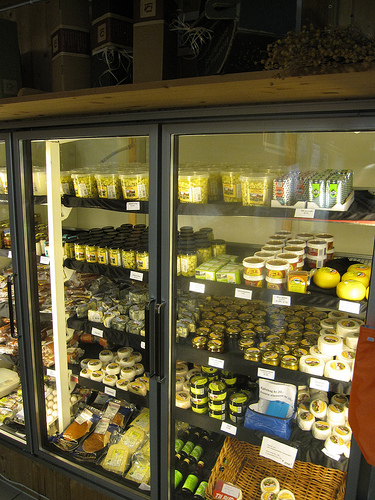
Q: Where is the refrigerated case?
A: In store.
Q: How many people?
A: None.